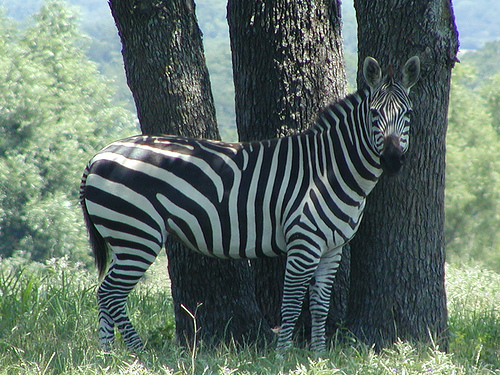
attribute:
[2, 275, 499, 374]
grass — green, shining, overgrown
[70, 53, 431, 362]
zebra — standing, black, white, staring, looking, striped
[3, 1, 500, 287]
trees — leafy, green, tall, brown, rough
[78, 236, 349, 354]
legs — black, white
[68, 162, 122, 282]
tail — frayed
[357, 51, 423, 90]
ears — pointed, sticking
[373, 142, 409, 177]
nose — black